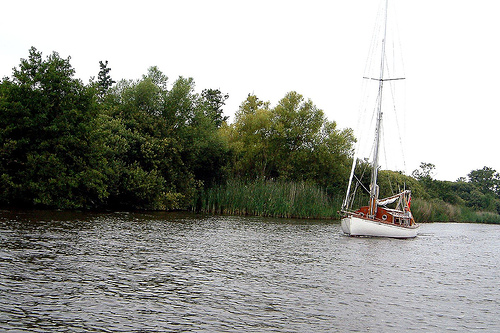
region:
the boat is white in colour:
[302, 163, 474, 268]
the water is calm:
[166, 237, 439, 329]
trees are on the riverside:
[11, 86, 329, 213]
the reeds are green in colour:
[230, 159, 305, 209]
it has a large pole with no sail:
[338, 8, 409, 178]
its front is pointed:
[302, 208, 392, 235]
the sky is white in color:
[112, 0, 316, 72]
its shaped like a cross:
[338, 31, 421, 191]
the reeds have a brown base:
[193, 183, 284, 230]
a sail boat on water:
[318, 1, 475, 264]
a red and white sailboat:
[331, 187, 429, 247]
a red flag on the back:
[402, 192, 421, 212]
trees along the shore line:
[11, 58, 360, 240]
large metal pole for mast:
[358, 9, 393, 219]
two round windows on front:
[356, 205, 398, 227]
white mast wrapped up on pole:
[374, 190, 412, 207]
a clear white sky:
[11, 0, 498, 182]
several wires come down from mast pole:
[355, 23, 419, 220]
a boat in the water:
[312, 185, 465, 265]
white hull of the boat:
[340, 212, 412, 245]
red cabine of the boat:
[357, 201, 407, 228]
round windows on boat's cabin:
[358, 207, 387, 227]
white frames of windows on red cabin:
[357, 206, 390, 222]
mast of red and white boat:
[358, 9, 404, 199]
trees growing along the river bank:
[14, 62, 496, 216]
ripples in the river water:
[25, 221, 499, 325]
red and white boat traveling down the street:
[340, 200, 414, 239]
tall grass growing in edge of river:
[197, 180, 331, 215]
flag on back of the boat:
[402, 193, 412, 210]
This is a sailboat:
[297, 144, 432, 251]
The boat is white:
[339, 174, 417, 278]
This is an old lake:
[125, 152, 274, 293]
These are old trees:
[42, 95, 142, 155]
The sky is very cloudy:
[148, 35, 300, 106]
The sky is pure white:
[183, 25, 292, 130]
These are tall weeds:
[193, 180, 344, 235]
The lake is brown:
[112, 288, 162, 323]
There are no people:
[215, 204, 420, 317]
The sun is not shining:
[187, 80, 409, 250]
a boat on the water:
[53, 47, 488, 256]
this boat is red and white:
[343, 56, 433, 263]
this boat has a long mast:
[341, 1, 404, 194]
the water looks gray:
[75, 218, 387, 306]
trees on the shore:
[29, 63, 337, 215]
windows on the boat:
[365, 203, 399, 226]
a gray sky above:
[213, 33, 364, 78]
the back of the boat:
[385, 188, 418, 209]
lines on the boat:
[381, 85, 417, 183]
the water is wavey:
[45, 222, 342, 326]